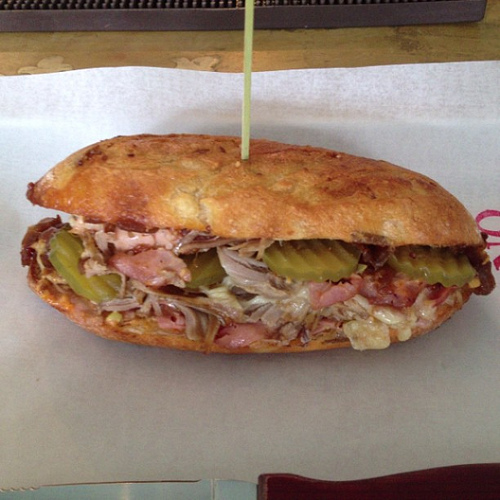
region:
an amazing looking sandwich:
[31, 124, 491, 376]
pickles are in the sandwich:
[51, 240, 487, 302]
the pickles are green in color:
[43, 232, 475, 307]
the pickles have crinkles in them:
[44, 231, 471, 303]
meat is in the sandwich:
[60, 214, 473, 340]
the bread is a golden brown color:
[49, 136, 484, 362]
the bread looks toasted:
[16, 140, 472, 360]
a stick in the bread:
[238, 4, 266, 158]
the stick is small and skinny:
[236, 0, 269, 159]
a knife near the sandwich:
[5, 455, 498, 495]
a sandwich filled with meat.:
[15, 132, 498, 356]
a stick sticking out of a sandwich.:
[237, 0, 262, 161]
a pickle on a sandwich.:
[250, 236, 365, 290]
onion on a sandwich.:
[137, 283, 282, 345]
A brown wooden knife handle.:
[257, 434, 495, 490]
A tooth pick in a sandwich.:
[235, 0, 269, 172]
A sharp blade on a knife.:
[0, 463, 270, 496]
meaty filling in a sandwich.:
[36, 202, 498, 347]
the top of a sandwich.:
[3, 137, 488, 274]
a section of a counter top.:
[241, 402, 322, 432]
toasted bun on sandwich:
[28, 133, 483, 250]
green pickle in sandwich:
[266, 243, 357, 276]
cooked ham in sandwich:
[116, 250, 189, 287]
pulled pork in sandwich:
[221, 247, 283, 299]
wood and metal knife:
[3, 460, 497, 498]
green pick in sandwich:
[240, 0, 252, 158]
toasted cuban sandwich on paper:
[24, 134, 486, 351]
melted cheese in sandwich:
[375, 290, 437, 342]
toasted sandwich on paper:
[22, 133, 491, 354]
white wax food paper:
[1, 65, 497, 480]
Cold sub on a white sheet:
[18, 133, 495, 361]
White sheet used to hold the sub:
[2, 65, 497, 482]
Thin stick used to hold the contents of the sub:
[238, 1, 256, 162]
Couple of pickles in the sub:
[262, 236, 477, 290]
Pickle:
[265, 243, 360, 280]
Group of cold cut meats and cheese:
[37, 208, 488, 350]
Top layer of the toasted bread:
[30, 129, 485, 249]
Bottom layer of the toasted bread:
[18, 222, 486, 357]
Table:
[0, 2, 498, 69]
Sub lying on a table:
[20, 139, 494, 357]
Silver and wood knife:
[3, 463, 497, 498]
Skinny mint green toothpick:
[231, 0, 270, 158]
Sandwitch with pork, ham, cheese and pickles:
[20, 133, 494, 353]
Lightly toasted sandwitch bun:
[16, 134, 491, 364]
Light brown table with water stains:
[1, 4, 498, 72]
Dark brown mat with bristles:
[3, 3, 484, 30]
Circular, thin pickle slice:
[46, 224, 131, 304]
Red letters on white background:
[462, 201, 499, 274]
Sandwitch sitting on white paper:
[1, 59, 497, 481]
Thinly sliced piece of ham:
[103, 238, 198, 295]